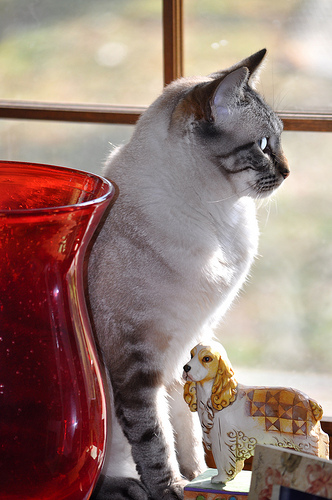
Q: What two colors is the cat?
A: Gray and white.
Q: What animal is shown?
A: A cat.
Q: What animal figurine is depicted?
A: A dog.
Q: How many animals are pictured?
A: One.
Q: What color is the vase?
A: Red.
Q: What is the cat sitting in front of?
A: A window.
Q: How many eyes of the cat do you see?
A: One.